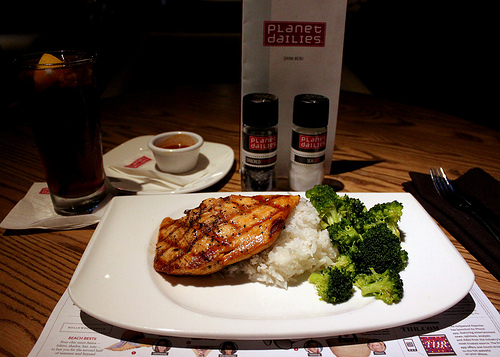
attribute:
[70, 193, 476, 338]
plate — square, white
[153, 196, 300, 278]
chicken — grilled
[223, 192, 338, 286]
rice — white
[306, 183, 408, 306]
broccoli — green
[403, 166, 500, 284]
napkin — brown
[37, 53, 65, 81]
lemon — yellow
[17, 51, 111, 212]
glass — dark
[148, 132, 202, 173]
sauce — white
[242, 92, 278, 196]
pepper — black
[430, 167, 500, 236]
fork — silver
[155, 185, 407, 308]
meal — ready, delicious, made, healthy, complete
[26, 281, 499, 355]
paper — white